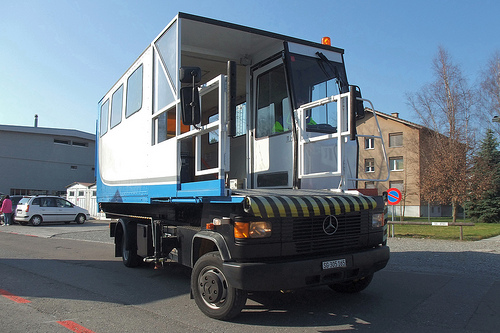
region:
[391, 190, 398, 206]
the sign is red and blue and red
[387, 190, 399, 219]
the sign is red and blue and red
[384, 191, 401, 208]
the sign is red and blue and red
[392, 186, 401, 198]
the sign is red and blue and red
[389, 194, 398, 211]
the sign is red and blue and red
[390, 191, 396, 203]
the sign is red and blue and red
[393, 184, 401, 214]
the sign is red and blue and red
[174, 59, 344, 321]
A truck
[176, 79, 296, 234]
A truck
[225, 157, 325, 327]
A truck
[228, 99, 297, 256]
A truck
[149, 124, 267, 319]
A truck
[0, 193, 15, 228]
woman in a pink coat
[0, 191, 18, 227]
woman in a pink coat standing on a street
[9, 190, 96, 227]
parked cars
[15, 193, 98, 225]
gray parked car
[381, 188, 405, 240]
round red and blue no sign on a pole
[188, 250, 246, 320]
black tire and black rims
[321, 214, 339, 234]
silver car brand logo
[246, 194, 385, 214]
striped design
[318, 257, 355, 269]
white license plate with dark color print on it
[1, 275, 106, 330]
red lines on the street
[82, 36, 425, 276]
truck with white and blue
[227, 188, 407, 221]
yellow and black caution band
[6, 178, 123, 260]
white van parked behind truck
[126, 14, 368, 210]
open truck on the street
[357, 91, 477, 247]
old building with windows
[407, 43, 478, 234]
dead trees near building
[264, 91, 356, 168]
man driving the truck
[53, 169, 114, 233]
sheds in front of cars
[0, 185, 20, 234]
woman in pink behind van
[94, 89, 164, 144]
windows on the truck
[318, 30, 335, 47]
Orange light on top of truck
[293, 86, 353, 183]
Open door on truck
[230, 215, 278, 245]
Front head light of car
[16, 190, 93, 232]
White minivan parked on lot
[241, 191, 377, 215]
Yellow and black bumper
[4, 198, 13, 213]
Woman wears pink sweater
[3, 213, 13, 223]
Woman wears blue jeans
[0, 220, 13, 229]
Woman wears white sneakers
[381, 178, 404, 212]
Blue and red sign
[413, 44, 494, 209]
Brown leave less trees